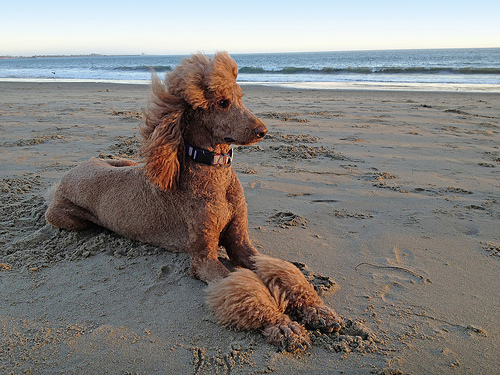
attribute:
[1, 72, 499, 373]
beach — wet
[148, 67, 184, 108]
dog's hair — blowing around